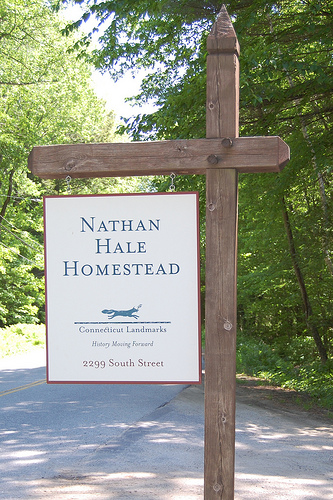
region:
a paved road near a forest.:
[0, 349, 331, 498]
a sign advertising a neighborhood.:
[57, 207, 199, 284]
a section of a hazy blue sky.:
[30, 0, 208, 142]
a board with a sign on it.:
[19, 129, 303, 180]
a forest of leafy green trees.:
[44, 0, 330, 401]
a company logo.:
[95, 294, 153, 319]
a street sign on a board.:
[75, 347, 176, 373]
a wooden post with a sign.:
[199, 7, 254, 498]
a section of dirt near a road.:
[236, 363, 331, 431]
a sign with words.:
[74, 319, 181, 336]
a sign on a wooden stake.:
[42, 185, 210, 390]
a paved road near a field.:
[0, 352, 330, 498]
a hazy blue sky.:
[35, 0, 278, 137]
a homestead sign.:
[42, 172, 202, 384]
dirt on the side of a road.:
[239, 373, 331, 424]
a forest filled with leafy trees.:
[43, 2, 331, 498]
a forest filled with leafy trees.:
[0, 0, 152, 361]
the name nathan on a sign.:
[76, 214, 179, 241]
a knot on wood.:
[216, 313, 237, 344]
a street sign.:
[71, 333, 166, 376]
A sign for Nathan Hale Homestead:
[38, 198, 205, 391]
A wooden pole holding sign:
[183, 287, 238, 499]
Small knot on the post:
[220, 316, 232, 333]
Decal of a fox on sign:
[93, 300, 152, 325]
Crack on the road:
[68, 407, 178, 484]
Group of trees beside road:
[171, 35, 327, 276]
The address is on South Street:
[73, 352, 175, 371]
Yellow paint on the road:
[4, 366, 34, 409]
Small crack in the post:
[216, 421, 232, 499]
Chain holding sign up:
[63, 168, 180, 192]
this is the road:
[9, 388, 75, 461]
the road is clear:
[23, 401, 74, 442]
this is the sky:
[106, 83, 125, 96]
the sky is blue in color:
[110, 83, 128, 101]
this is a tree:
[289, 4, 330, 377]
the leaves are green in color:
[253, 202, 277, 280]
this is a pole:
[204, 391, 235, 494]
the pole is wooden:
[206, 410, 225, 488]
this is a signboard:
[38, 196, 202, 382]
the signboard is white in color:
[148, 275, 175, 299]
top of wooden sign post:
[17, 4, 289, 205]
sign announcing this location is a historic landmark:
[33, 189, 204, 386]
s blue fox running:
[101, 301, 142, 321]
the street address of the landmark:
[76, 356, 169, 372]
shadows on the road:
[8, 364, 331, 495]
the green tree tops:
[4, 0, 329, 141]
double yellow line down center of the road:
[0, 374, 46, 406]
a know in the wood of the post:
[50, 152, 90, 172]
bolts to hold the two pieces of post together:
[200, 118, 257, 186]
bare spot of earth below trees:
[236, 370, 331, 442]